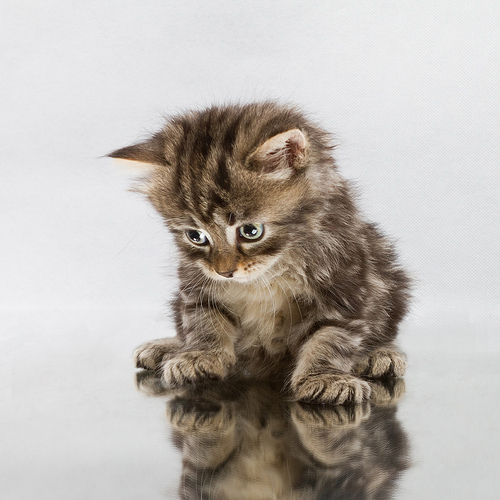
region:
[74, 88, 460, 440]
a cat in the picture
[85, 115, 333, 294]
the cat is looking down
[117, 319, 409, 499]
the cat's reflection on the table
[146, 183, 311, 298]
the cat is looking at the table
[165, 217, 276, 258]
the cat's eyes is blue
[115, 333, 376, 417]
the cat's paws are on the table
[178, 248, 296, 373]
the cat has whiskers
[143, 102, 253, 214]
this cat has black stripes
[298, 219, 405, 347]
this cat has brown and black fur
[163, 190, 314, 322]
the cat has white highlights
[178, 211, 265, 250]
eyes of the cat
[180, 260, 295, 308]
mustache of the cat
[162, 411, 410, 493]
reflection of the cat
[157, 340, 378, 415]
front leg of the cat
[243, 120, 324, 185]
ear of the cat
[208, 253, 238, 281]
nostril of the cat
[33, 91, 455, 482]
a cat sitting in the floor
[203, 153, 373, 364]
black and brown color cat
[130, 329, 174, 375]
back leg of the cat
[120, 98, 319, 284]
head of the cat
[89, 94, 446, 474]
kitten on a reflective surface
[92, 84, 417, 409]
a small tabby kitten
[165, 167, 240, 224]
forehead markings of a tabby cat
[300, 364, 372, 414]
small forepaw of a kitten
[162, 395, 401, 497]
reflection of small tabby kitten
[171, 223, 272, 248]
kittens eyes are dilated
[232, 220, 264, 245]
kittens eye is golden green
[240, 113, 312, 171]
tufty ear of kitten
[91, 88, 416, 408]
this kitten is dark and light brown with black markings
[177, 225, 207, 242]
The left eye of the kitten.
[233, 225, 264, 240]
The right eye of the kitten.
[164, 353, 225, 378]
The front left paw of the kitten.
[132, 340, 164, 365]
The back left paw of the kitten.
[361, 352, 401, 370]
The back right paw of the kitten.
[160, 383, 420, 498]
The reflection of the kitten.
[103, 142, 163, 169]
The kitten's left ear.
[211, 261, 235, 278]
The nose of the kitten.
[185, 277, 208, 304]
brown fur on cat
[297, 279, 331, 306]
brown fur on cat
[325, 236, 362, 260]
brown fur on cat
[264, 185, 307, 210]
brown fur on cat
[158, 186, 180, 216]
brown fur on cat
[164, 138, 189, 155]
brown fur on cat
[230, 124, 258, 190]
brown fur on cat